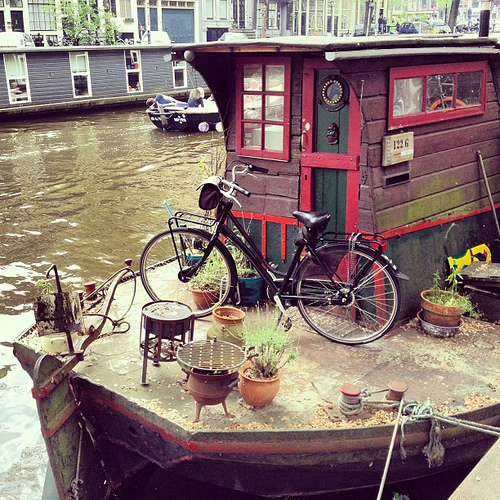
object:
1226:
[394, 138, 410, 149]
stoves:
[139, 300, 240, 423]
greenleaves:
[41, 0, 120, 45]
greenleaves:
[378, 0, 452, 33]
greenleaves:
[190, 247, 228, 290]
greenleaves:
[426, 269, 485, 319]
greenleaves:
[221, 300, 300, 379]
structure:
[187, 46, 430, 290]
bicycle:
[138, 164, 409, 346]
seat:
[292, 210, 331, 233]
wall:
[227, 84, 245, 130]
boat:
[10, 9, 500, 500]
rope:
[338, 386, 500, 500]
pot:
[237, 360, 280, 409]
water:
[0, 103, 233, 500]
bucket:
[239, 277, 263, 306]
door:
[303, 67, 352, 320]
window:
[235, 58, 291, 162]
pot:
[420, 289, 467, 327]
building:
[162, 33, 499, 333]